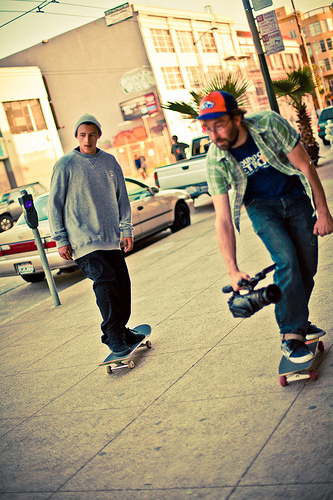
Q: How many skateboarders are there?
A: Two.